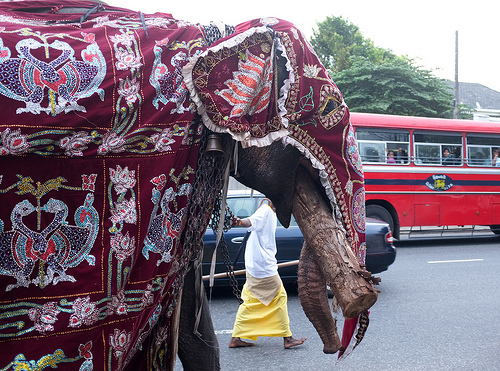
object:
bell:
[204, 132, 227, 157]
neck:
[196, 22, 244, 161]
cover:
[171, 58, 254, 121]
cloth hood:
[187, 15, 377, 359]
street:
[202, 219, 497, 371]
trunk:
[294, 236, 362, 359]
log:
[296, 167, 384, 318]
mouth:
[280, 161, 336, 230]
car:
[197, 190, 397, 297]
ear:
[179, 22, 308, 145]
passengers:
[364, 144, 496, 163]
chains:
[183, 124, 245, 308]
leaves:
[346, 51, 430, 114]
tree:
[304, 10, 465, 120]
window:
[409, 129, 464, 167]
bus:
[346, 111, 498, 241]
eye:
[319, 96, 341, 119]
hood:
[0, 0, 380, 371]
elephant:
[156, 12, 376, 363]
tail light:
[385, 230, 394, 246]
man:
[225, 199, 304, 352]